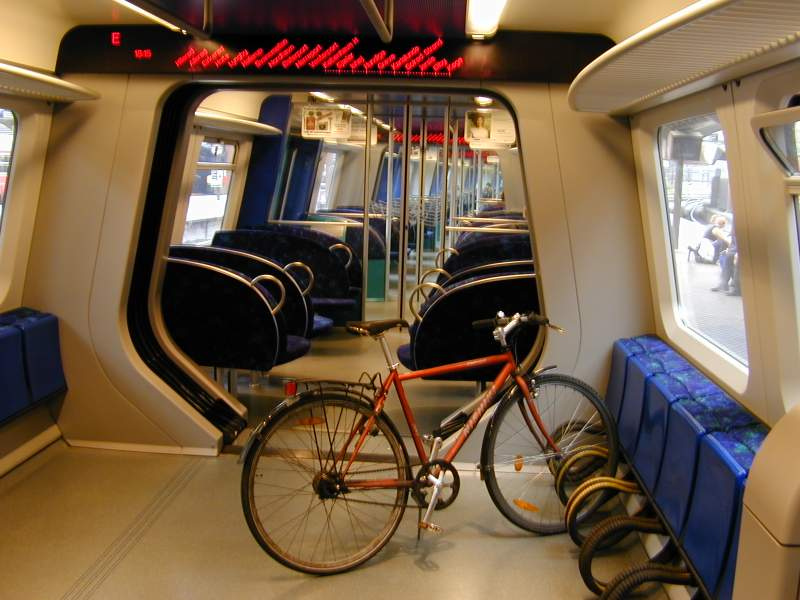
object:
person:
[698, 215, 741, 296]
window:
[657, 112, 749, 368]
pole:
[362, 90, 374, 322]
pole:
[385, 102, 396, 302]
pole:
[399, 95, 412, 332]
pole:
[440, 105, 450, 269]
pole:
[459, 145, 466, 217]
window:
[759, 119, 799, 176]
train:
[0, 0, 800, 600]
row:
[162, 93, 544, 382]